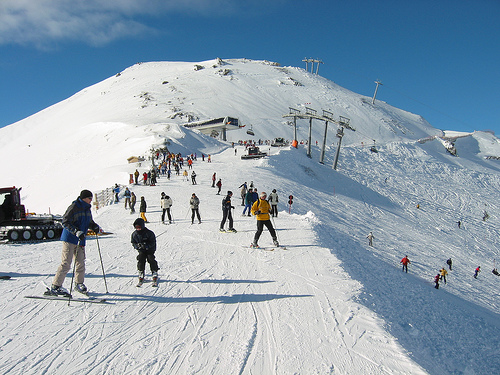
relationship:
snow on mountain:
[61, 101, 278, 331] [4, 54, 489, 373]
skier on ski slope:
[60, 190, 95, 308] [4, 65, 472, 374]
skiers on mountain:
[124, 150, 278, 233] [4, 54, 489, 373]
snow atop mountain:
[61, 101, 278, 331] [4, 54, 489, 373]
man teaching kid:
[56, 177, 91, 289] [128, 204, 167, 289]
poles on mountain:
[278, 105, 349, 169] [4, 54, 489, 373]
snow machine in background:
[241, 147, 262, 160] [6, 2, 474, 257]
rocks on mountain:
[195, 60, 301, 83] [4, 54, 489, 373]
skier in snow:
[60, 190, 95, 308] [61, 101, 278, 331]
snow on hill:
[61, 101, 278, 331] [441, 126, 499, 161]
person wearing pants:
[253, 190, 276, 245] [255, 216, 277, 245]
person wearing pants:
[68, 176, 96, 287] [52, 240, 88, 290]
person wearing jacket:
[155, 185, 172, 225] [159, 196, 175, 208]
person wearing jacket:
[400, 254, 410, 268] [400, 254, 412, 265]